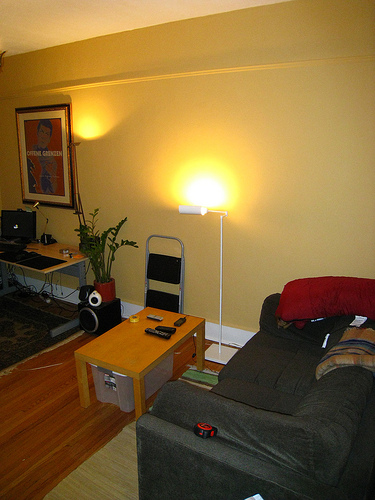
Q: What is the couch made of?
A: Dark gray material.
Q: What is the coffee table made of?
A: Light wood.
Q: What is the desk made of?
A: Light wood.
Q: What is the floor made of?
A: Wood.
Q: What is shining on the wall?
A: A light.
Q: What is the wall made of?
A: Sheet rock.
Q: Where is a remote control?
A: On coffee table.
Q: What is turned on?
A: Lights.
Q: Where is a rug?
A: On the floor.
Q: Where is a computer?
A: On a desk.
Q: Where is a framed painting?
A: On the wall.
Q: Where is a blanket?
A: On top of a couch.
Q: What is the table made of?
A: Wood.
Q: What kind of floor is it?
A: Wood.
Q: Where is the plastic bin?
A: Under table.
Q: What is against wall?
A: Folded stool.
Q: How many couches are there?
A: One.